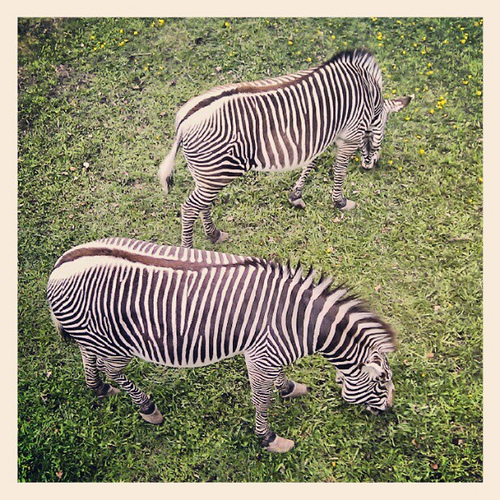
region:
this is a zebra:
[141, 32, 428, 250]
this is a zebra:
[44, 225, 406, 459]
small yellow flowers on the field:
[384, 140, 441, 185]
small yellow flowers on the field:
[417, 88, 455, 131]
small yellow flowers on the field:
[441, 31, 474, 78]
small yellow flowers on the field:
[81, 28, 118, 68]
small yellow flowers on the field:
[266, 26, 327, 65]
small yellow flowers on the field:
[401, 37, 461, 94]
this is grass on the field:
[404, 388, 469, 462]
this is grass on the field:
[367, 283, 461, 363]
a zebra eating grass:
[36, 230, 395, 455]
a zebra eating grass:
[138, 48, 407, 248]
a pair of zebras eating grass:
[44, 44, 455, 459]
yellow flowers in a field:
[348, 16, 490, 203]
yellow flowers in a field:
[63, 21, 273, 86]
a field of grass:
[17, 21, 484, 483]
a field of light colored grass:
[93, 34, 461, 353]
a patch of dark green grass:
[18, 377, 117, 484]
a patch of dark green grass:
[362, 392, 482, 482]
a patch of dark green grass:
[18, 17, 85, 81]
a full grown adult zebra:
[30, 221, 435, 452]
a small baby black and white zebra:
[136, 77, 426, 240]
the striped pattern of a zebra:
[117, 243, 189, 328]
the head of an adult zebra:
[323, 281, 390, 397]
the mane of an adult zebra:
[310, 275, 386, 342]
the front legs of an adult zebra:
[221, 345, 321, 455]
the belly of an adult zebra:
[147, 322, 211, 379]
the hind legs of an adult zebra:
[97, 356, 172, 440]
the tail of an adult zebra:
[44, 302, 86, 370]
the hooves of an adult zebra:
[267, 428, 325, 480]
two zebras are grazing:
[65, 47, 422, 443]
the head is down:
[285, 277, 425, 447]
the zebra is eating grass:
[287, 277, 417, 438]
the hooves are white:
[255, 418, 310, 465]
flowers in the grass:
[405, 73, 460, 188]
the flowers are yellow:
[407, 40, 479, 173]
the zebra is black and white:
[7, 191, 392, 392]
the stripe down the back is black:
[32, 230, 271, 288]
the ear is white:
[344, 349, 388, 392]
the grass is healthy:
[309, 213, 459, 423]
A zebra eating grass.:
[155, 44, 410, 246]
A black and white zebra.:
[45, 235, 400, 451]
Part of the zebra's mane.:
[316, 280, 348, 297]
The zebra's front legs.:
[243, 352, 305, 456]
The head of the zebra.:
[336, 350, 398, 413]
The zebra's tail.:
[47, 308, 73, 343]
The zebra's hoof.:
[138, 405, 165, 425]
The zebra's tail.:
[156, 133, 180, 193]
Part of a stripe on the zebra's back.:
[269, 82, 284, 94]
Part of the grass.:
[200, 400, 222, 458]